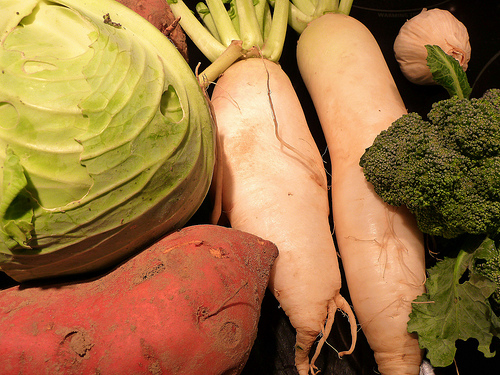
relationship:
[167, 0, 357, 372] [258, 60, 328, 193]
carrot has split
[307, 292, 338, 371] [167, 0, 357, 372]
root on bottom of carrot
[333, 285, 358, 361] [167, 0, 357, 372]
root on bottom of carrot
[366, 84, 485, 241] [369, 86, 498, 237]
broccoli has head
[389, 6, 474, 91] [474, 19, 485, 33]
garlic on top of table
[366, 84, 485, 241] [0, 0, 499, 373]
broccoli on top of table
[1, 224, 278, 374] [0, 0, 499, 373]
sweet potato on top of table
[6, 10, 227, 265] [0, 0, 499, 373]
cabbage on top of table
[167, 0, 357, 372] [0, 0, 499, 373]
carrot on top of table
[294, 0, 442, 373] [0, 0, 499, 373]
carrots on top of table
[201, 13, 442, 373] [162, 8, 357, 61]
carrots with stems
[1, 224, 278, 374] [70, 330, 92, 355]
sweet potato with dirt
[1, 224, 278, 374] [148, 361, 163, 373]
sweet potato with dirt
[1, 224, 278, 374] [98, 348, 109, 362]
sweet potato with dirt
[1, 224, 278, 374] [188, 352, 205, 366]
sweet potato with dirt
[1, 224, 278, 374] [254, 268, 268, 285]
sweet potato with dirt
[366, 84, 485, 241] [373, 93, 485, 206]
broccoli has head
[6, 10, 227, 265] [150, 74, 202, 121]
cabbage has hole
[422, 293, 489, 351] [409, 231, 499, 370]
leaf of spinach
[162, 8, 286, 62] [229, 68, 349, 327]
stems of vegetables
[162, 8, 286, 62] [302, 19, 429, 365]
stems of vegetables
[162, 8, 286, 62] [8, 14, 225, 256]
stems of vegetables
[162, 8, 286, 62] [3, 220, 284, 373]
stems of vegetables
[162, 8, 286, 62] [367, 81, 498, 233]
stems of vegetables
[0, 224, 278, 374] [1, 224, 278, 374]
dirt on sweet potato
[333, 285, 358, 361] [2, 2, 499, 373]
root of vegetable